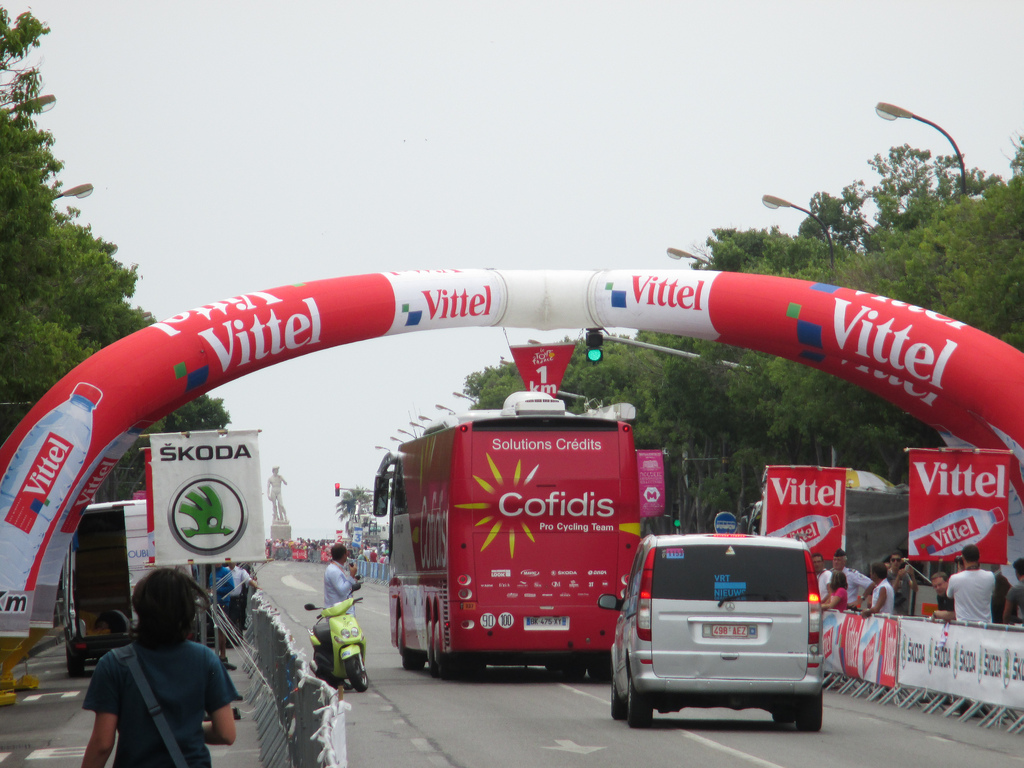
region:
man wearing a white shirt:
[863, 563, 893, 614]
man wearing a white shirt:
[818, 547, 872, 605]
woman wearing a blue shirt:
[82, 566, 242, 766]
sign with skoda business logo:
[141, 433, 266, 563]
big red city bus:
[372, 389, 645, 675]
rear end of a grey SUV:
[597, 532, 825, 728]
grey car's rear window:
[653, 544, 812, 599]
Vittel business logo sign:
[904, 448, 1007, 566]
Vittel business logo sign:
[762, 465, 848, 561]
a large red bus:
[381, 424, 648, 665]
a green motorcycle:
[306, 595, 370, 678]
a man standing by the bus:
[321, 546, 350, 588]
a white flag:
[151, 439, 268, 553]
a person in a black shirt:
[101, 578, 226, 721]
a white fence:
[822, 612, 1020, 699]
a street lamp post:
[866, 98, 930, 138]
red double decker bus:
[359, 382, 647, 684]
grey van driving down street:
[597, 527, 835, 740]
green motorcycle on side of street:
[291, 584, 378, 698]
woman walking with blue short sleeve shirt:
[78, 563, 247, 766]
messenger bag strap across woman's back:
[103, 638, 209, 766]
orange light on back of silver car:
[800, 584, 826, 608]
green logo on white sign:
[160, 478, 240, 551]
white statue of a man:
[258, 458, 306, 544]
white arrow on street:
[525, 727, 617, 763]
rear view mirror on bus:
[363, 448, 402, 528]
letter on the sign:
[232, 322, 261, 358]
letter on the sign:
[253, 315, 270, 355]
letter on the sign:
[291, 318, 308, 344]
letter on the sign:
[416, 275, 446, 320]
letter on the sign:
[636, 266, 652, 305]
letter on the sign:
[902, 347, 951, 393]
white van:
[606, 505, 832, 761]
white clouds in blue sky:
[99, 0, 180, 91]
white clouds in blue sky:
[327, 43, 476, 146]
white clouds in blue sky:
[470, 47, 531, 111]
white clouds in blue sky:
[336, 183, 436, 257]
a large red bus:
[368, 430, 640, 675]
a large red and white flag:
[904, 452, 1010, 558]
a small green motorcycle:
[301, 597, 374, 687]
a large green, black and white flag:
[155, 430, 266, 568]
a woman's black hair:
[124, 568, 204, 648]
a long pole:
[596, 329, 745, 372]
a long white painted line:
[677, 717, 775, 766]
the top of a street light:
[877, 101, 970, 182]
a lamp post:
[867, 100, 963, 162]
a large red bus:
[386, 402, 625, 663]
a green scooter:
[301, 601, 356, 677]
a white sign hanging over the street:
[157, 434, 255, 559]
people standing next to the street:
[807, 541, 1004, 622]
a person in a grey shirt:
[86, 571, 233, 758]